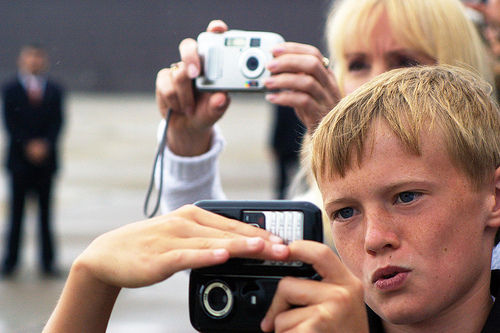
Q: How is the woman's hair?
A: Straight.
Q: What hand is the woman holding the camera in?
A: Both hands.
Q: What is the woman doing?
A: Taking a picture.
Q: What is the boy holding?
A: Cell phone.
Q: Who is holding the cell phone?
A: The boy.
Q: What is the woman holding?
A: Camera.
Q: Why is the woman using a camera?
A: Take picture.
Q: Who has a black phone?
A: Boy in front.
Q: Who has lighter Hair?
A: The woman.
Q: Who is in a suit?
A: Blurred man on left.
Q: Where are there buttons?
A: Boy's phone.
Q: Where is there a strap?
A: Woman's camera.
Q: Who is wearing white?
A: The woman.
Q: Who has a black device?
A: The boy.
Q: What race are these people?
A: Caucasians.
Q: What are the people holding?
A: Cameras.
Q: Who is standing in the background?
A: A man.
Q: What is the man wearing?
A: A black suit.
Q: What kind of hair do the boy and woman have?
A: Blond.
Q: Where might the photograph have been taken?
A: A tarmac.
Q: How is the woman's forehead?
A: Wrinkled.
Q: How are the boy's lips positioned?
A: Pursed.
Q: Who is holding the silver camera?
A: A woman.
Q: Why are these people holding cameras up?
A: To take a picture.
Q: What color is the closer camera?
A: Black.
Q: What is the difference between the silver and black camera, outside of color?
A: The black camera is also a phone.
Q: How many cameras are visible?
A: Two.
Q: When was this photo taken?
A: Outside, during the daytime.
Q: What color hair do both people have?
A: Blond.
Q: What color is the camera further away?
A: Silver.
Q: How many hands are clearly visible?
A: Four.